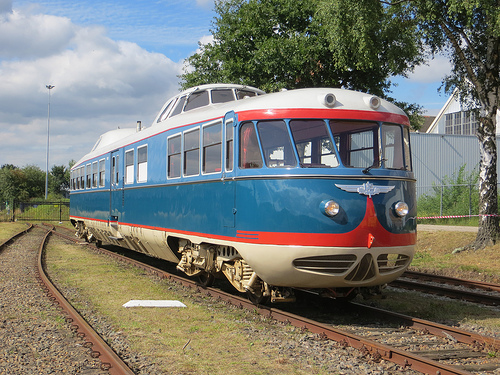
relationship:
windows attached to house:
[441, 117, 465, 132] [433, 96, 474, 135]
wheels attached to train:
[170, 240, 250, 284] [69, 120, 349, 306]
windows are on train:
[441, 117, 465, 132] [69, 120, 349, 306]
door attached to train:
[105, 145, 124, 216] [69, 120, 349, 306]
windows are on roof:
[441, 117, 465, 132] [178, 78, 226, 113]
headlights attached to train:
[304, 195, 421, 229] [69, 120, 349, 306]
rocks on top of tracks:
[50, 350, 72, 374] [417, 266, 475, 371]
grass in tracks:
[118, 302, 142, 319] [417, 266, 475, 371]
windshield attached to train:
[330, 122, 379, 164] [69, 120, 349, 306]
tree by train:
[268, 10, 344, 71] [69, 120, 349, 306]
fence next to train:
[422, 130, 472, 177] [69, 120, 349, 306]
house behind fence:
[433, 96, 474, 135] [422, 130, 472, 177]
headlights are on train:
[304, 195, 421, 229] [69, 120, 349, 306]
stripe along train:
[112, 214, 176, 236] [69, 120, 349, 306]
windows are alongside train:
[441, 117, 465, 132] [69, 120, 349, 306]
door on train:
[105, 145, 124, 216] [69, 120, 349, 306]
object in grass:
[131, 294, 159, 313] [118, 302, 142, 319]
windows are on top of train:
[441, 117, 465, 132] [69, 120, 349, 306]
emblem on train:
[335, 177, 380, 198] [69, 120, 349, 306]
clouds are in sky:
[13, 21, 103, 92] [186, 4, 196, 30]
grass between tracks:
[118, 302, 142, 319] [417, 266, 475, 371]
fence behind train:
[422, 130, 472, 177] [69, 120, 349, 306]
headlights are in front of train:
[304, 195, 421, 229] [69, 120, 349, 306]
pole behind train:
[43, 88, 53, 206] [69, 120, 349, 306]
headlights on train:
[393, 200, 411, 219] [66, 79, 415, 304]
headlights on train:
[321, 200, 341, 214] [66, 79, 415, 304]